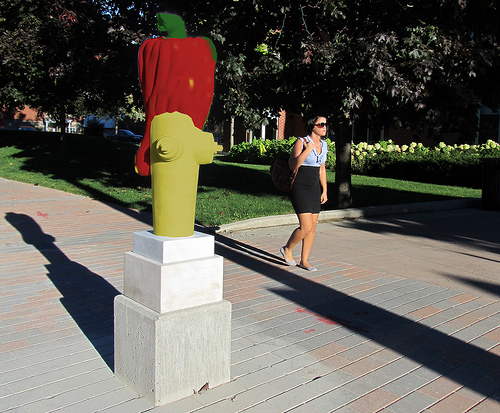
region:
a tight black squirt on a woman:
[292, 165, 325, 215]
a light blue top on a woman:
[299, 136, 328, 167]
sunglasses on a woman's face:
[313, 122, 330, 130]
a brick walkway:
[1, 177, 499, 408]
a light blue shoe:
[278, 244, 297, 267]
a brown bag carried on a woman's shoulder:
[265, 133, 311, 199]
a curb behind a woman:
[217, 194, 478, 234]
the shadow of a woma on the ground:
[137, 197, 294, 266]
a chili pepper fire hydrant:
[121, 4, 235, 251]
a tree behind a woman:
[221, 0, 493, 200]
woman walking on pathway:
[260, 58, 397, 386]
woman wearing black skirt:
[285, 156, 333, 223]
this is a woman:
[271, 100, 356, 288]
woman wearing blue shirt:
[285, 127, 335, 179]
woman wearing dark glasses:
[308, 118, 331, 132]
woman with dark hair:
[298, 110, 329, 132]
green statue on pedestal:
[142, 87, 229, 243]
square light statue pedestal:
[102, 204, 242, 398]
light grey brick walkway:
[265, 334, 351, 408]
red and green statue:
[120, 4, 237, 206]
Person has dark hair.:
[306, 110, 318, 126]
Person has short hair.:
[304, 110, 340, 144]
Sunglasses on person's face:
[311, 119, 335, 137]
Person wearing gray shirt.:
[298, 135, 340, 176]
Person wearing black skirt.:
[294, 175, 334, 214]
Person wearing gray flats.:
[274, 245, 336, 284]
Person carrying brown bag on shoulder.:
[272, 140, 321, 184]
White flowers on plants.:
[381, 139, 408, 153]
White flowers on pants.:
[430, 135, 473, 148]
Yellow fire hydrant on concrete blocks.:
[152, 124, 214, 241]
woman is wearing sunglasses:
[305, 112, 332, 147]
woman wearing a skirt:
[289, 159, 327, 219]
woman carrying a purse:
[270, 145, 296, 202]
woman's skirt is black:
[289, 163, 330, 221]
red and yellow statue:
[110, 10, 224, 230]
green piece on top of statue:
[152, 6, 218, 61]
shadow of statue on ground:
[3, 205, 120, 376]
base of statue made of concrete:
[101, 290, 233, 404]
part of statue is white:
[111, 219, 230, 308]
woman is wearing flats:
[275, 242, 324, 277]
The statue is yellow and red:
[135, 20, 217, 240]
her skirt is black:
[295, 171, 321, 216]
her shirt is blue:
[297, 136, 331, 163]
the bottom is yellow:
[137, 105, 237, 233]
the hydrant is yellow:
[145, 106, 221, 211]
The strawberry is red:
[129, 27, 214, 178]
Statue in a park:
[54, 77, 419, 380]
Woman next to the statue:
[268, 106, 340, 279]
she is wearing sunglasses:
[306, 110, 334, 135]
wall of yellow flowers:
[345, 126, 486, 164]